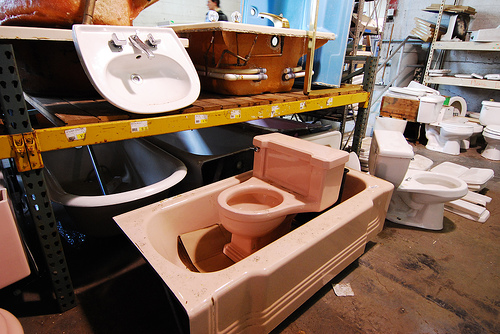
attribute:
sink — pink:
[209, 157, 323, 251]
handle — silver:
[248, 144, 262, 153]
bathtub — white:
[40, 139, 187, 206]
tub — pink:
[102, 147, 446, 319]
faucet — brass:
[106, 30, 176, 63]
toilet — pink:
[211, 119, 377, 260]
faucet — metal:
[107, 29, 165, 65]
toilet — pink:
[194, 125, 369, 277]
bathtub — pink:
[110, 157, 422, 332]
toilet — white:
[361, 113, 478, 232]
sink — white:
[74, 21, 202, 114]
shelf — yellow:
[2, 80, 372, 170]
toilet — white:
[380, 120, 469, 257]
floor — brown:
[381, 244, 466, 325]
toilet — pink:
[476, 99, 498, 166]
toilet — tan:
[243, 129, 344, 236]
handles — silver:
[110, 30, 161, 50]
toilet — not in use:
[221, 130, 348, 257]